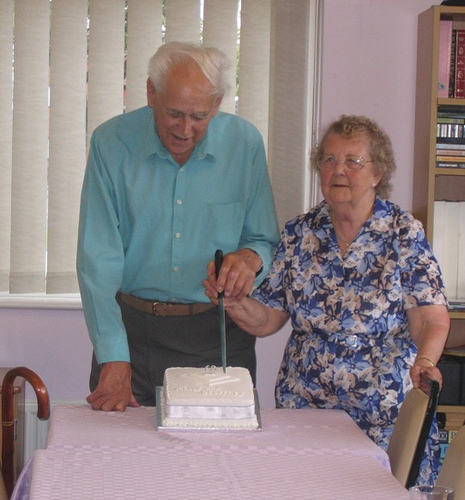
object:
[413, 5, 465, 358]
bookcase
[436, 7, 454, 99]
books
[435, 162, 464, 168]
cassette tapes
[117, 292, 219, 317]
belt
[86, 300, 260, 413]
pants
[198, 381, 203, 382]
frosting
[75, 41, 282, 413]
person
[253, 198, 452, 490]
dress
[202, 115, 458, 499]
woman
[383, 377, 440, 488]
chair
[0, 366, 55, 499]
cane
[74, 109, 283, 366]
shirt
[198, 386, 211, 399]
frosting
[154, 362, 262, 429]
cake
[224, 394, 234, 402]
icing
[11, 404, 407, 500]
table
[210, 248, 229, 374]
knife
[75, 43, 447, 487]
couple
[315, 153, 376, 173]
eyeglasses